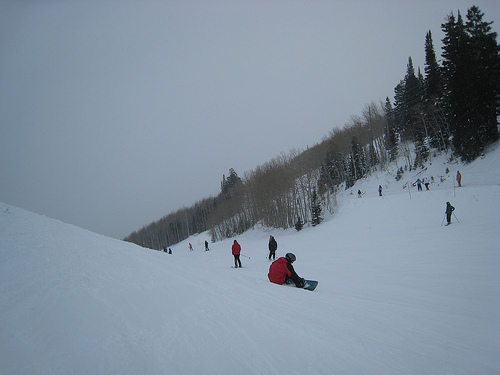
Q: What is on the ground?
A: Snow.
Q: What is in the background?
A: Many trees.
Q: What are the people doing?
A: Snowboarding and skiing.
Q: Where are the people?
A: In the snow.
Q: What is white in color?
A: The snow.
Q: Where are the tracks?
A: In the snow.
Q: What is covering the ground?
A: Snow.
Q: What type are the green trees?
A: Pine trees.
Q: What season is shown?
A: Winter.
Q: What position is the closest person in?
A: Sitting.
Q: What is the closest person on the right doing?
A: Skiing.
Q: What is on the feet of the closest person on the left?
A: Snowboard.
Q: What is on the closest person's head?
A: Helmet.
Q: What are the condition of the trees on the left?
A: Bare.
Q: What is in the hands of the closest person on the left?
A: Ski poles.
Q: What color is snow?
A: White.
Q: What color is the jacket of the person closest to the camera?
A: Red.